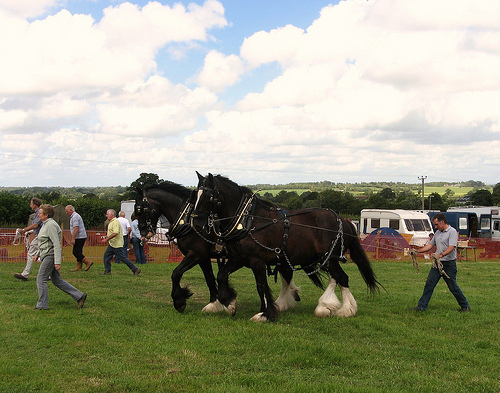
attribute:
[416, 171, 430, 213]
post — electric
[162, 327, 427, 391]
grass — green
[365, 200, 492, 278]
car — white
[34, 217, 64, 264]
shirt — green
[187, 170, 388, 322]
horse — white, brown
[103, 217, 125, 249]
shirt — yellow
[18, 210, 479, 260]
fence — orange, plastic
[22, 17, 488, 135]
clouds — white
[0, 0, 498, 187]
clouds — white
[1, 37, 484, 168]
clouds — white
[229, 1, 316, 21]
sky — blue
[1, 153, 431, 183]
line — electric